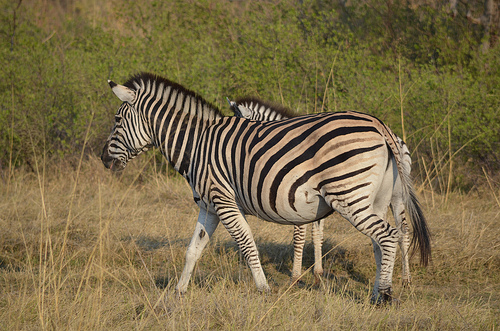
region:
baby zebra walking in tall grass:
[228, 88, 425, 295]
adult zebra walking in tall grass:
[98, 69, 436, 294]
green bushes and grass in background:
[2, 0, 497, 175]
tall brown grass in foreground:
[8, 150, 498, 326]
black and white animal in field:
[94, 73, 442, 306]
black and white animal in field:
[231, 96, 422, 294]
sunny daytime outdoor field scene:
[4, 7, 499, 322]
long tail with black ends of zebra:
[373, 125, 438, 263]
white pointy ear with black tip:
[103, 73, 133, 101]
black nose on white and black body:
[101, 140, 121, 165]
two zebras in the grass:
[77, 61, 458, 324]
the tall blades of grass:
[10, 139, 162, 319]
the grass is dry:
[33, 153, 171, 298]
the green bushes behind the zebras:
[3, 24, 498, 137]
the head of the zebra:
[78, 72, 189, 177]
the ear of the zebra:
[97, 73, 139, 107]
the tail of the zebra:
[364, 109, 442, 267]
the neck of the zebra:
[136, 108, 206, 173]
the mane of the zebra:
[122, 68, 229, 125]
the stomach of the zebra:
[221, 178, 337, 225]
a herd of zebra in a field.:
[97, 45, 442, 317]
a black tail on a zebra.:
[406, 188, 446, 276]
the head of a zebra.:
[93, 63, 163, 169]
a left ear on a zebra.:
[101, 65, 143, 117]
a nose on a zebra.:
[96, 133, 123, 174]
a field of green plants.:
[4, 0, 498, 175]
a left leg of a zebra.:
[212, 193, 281, 291]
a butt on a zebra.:
[317, 96, 419, 316]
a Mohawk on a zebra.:
[207, 78, 304, 135]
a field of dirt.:
[1, 159, 498, 329]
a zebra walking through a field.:
[86, 74, 436, 303]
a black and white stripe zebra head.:
[94, 70, 158, 178]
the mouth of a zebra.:
[95, 128, 124, 170]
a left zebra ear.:
[106, 70, 144, 107]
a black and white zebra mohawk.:
[118, 58, 224, 131]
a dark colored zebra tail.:
[400, 196, 445, 267]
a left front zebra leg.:
[189, 175, 284, 291]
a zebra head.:
[94, 73, 183, 183]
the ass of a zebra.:
[304, 110, 408, 244]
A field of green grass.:
[1, 0, 498, 177]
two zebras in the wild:
[22, 12, 425, 322]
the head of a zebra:
[86, 70, 161, 172]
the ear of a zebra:
[105, 74, 138, 107]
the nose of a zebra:
[98, 142, 122, 170]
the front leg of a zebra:
[172, 209, 215, 294]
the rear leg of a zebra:
[345, 204, 402, 301]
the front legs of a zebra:
[162, 205, 275, 293]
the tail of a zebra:
[381, 121, 441, 266]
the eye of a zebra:
[111, 113, 126, 126]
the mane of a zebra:
[125, 70, 221, 125]